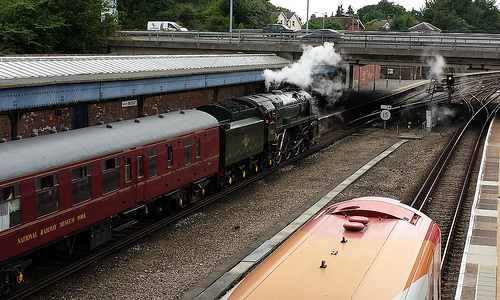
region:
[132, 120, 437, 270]
Trains parked in the railway station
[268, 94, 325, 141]
Engine of the train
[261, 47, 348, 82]
White color smoke of the train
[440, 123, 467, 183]
Train track near the platform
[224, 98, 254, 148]
Black color coal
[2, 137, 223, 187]
Lot of windows in the train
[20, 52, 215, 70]
White color metal sheet roof in the railway station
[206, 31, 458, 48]
Over bridge above the train track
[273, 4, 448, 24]
Lot of buildings near the railway station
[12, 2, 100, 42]
Lot of trees with its branches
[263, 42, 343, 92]
Large amount of white smoke coming out of a green train.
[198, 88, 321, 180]
Green train with green car behind the front.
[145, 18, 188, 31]
White van on the bridge.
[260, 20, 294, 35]
Black suv on the bridge ahead of the white van.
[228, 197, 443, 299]
Orange, red and white train.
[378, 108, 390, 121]
Round sign that says 15 on it.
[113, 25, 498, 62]
Concrete bridge with traffic driving on top.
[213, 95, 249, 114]
Black coal in the green car.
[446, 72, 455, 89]
Black traffic light on the right with a light illuminated.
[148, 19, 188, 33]
White van on the road above the trains.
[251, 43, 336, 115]
smoke coming from a train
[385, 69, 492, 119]
several train tracks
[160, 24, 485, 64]
a concrete bridge over train tracks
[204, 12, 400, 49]
two cars crossing a bridge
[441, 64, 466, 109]
a signal light on a train track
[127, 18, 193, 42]
a white van crossing over a bridge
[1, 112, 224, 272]
a red train car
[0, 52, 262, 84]
a metal roof of a building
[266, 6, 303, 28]
a yellow house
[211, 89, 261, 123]
black coal on a train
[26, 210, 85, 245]
writing on the train.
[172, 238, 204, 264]
pebbles between the tracks.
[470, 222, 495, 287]
edge of the platform.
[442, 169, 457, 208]
wooden slats between tracks.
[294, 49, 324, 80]
steam coming from train.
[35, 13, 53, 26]
leaves on the tree.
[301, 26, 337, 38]
car on the bridge.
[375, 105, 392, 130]
sign near the tracks.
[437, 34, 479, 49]
railing on the bridge.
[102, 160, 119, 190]
window on the train.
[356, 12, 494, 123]
bridge over railroad tracks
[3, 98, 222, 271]
red passenger car of train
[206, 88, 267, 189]
filled train coal car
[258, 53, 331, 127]
smoke coming from train engine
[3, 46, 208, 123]
roof of train platform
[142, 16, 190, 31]
top half of white panel van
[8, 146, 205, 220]
row of windows on train car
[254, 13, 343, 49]
two cars going opposite directions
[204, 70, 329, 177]
steam engine and coal car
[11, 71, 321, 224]
steam engine pulling passenger car